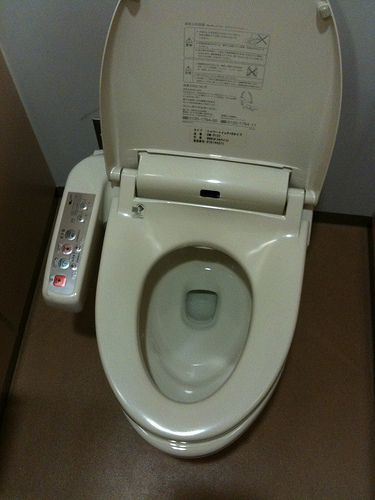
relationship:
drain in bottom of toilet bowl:
[181, 276, 226, 324] [105, 215, 305, 440]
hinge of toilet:
[106, 134, 354, 256] [52, 37, 324, 417]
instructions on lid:
[182, 19, 271, 146] [93, 3, 342, 211]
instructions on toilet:
[182, 19, 271, 146] [46, 47, 342, 458]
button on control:
[47, 268, 73, 290] [43, 190, 91, 300]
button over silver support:
[53, 202, 87, 286] [43, 189, 100, 308]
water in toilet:
[135, 240, 255, 405] [40, 1, 347, 455]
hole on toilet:
[198, 188, 220, 200] [40, 1, 347, 455]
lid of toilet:
[93, 3, 342, 211] [40, 1, 347, 455]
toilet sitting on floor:
[68, 95, 318, 487] [304, 340, 367, 475]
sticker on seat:
[131, 203, 145, 220] [92, 166, 317, 442]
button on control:
[53, 202, 87, 286] [50, 170, 85, 301]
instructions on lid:
[172, 14, 276, 160] [93, 3, 342, 211]